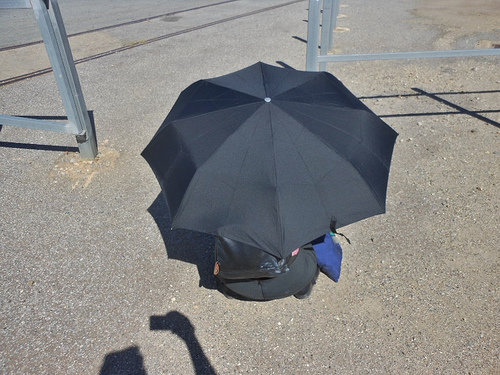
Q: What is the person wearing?
A: Black pants.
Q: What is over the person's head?
A: An umbrella.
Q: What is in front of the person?
A: A silver frame.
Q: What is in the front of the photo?
A: The shadow of the picture taker.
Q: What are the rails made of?
A: Metal.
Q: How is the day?
A: Sunny.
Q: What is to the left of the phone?
A: A grey metal gate.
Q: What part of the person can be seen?
A: Rear end and shoes.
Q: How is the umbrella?
A: Open.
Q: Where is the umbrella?
A: Over the person.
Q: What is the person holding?
A: Umbrella.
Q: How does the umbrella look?
A: Black and dry.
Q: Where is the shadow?
A: On the ground.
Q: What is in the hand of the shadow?
A: A camera.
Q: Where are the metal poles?
A: By the person.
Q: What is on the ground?
A: Gravel.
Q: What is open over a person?
A: An umbrella.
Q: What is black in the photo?
A: An umbrella.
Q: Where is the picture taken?
A: A street.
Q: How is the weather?
A: Sunny.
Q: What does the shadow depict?
A: A person.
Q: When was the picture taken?
A: During the day.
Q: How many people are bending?
A: 1.